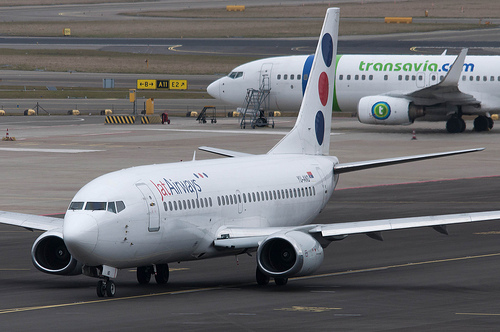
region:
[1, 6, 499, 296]
airplane is driving on landing gear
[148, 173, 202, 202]
jatAirways is painted on bus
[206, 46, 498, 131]
plane in back has ladder to it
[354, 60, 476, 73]
plane says transavia.com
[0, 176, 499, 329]
black runway in shot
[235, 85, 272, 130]
metal stairs pulled up to door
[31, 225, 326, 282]
closest jet has turbine engines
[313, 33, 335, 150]
three dots on tail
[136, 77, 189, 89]
black and yellow markings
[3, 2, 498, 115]
tarmac has several runways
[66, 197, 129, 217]
the windshield of a plane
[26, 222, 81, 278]
the engine of a plane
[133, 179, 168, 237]
the door of a plane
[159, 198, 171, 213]
a window on the plane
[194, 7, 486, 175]
the tail of a plane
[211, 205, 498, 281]
the wing of a plane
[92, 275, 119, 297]
the wheel of a plane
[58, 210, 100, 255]
the nose of a plane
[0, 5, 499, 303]
a white plane on the ground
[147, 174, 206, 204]
writing on the plane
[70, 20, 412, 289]
plane is white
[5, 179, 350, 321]
plane has two engines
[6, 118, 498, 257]
plane has white wings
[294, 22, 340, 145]
red and blue dots on tail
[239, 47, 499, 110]
white, green, and blue plane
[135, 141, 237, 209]
red and blue company name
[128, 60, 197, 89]
yellow and black sign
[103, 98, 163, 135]
yellow and black barrier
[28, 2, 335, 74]
brown ground behind planes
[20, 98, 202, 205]
tarmac is light grey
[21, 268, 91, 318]
white line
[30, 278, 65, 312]
white line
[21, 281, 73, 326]
white line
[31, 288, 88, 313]
white line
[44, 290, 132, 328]
white line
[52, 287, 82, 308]
white line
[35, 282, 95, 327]
white line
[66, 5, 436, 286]
Airplane has three dots on tail.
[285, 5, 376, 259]
Red and blue dots.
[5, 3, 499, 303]
Plane belongs to Jet Airways.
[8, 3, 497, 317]
The plane is white.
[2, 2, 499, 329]
Plane is on the tarmac.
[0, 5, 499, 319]
The plane is grounded.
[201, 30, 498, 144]
Plane is green white and blue.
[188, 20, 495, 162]
Portable stairs by plane.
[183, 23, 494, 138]
Blue and green strip around plane.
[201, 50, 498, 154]
Plane sitting on tarmac.